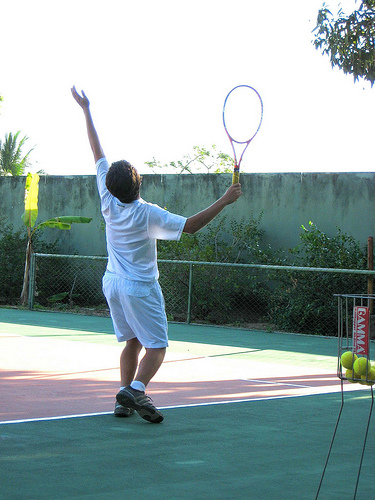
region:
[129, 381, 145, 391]
a short white sock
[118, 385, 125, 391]
a short white sock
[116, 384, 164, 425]
a brown and black tennis shoe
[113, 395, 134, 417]
a brown and black tennis shoe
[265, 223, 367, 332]
a large green bush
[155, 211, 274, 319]
a large green bush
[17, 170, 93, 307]
a large leafed plant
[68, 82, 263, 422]
a tennis player serving ball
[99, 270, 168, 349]
a pair of men's white shorts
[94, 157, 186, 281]
a man's short sleeve white t-shirt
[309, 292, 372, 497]
a metal basket with tennis balls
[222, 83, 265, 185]
a red black and yellow tennis racket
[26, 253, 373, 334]
a short chain link fence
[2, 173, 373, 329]
a tall concrete wall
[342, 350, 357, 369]
a bright yellow tennis ball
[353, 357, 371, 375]
a bright yellow tennis ball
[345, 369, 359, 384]
a bright yellow tennis ball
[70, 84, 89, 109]
A man's left hand.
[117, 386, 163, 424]
A man's right sneaker that is brown and black.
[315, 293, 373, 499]
A metal container that is holding tennis balls.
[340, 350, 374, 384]
Four tennis balls in a metal basket.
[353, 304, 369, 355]
A red sign with white letters that say GAMMA.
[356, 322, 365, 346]
Double white M's in GAMMA.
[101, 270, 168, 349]
White shorts on a man serving.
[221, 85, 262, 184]
A blue and red tennis racket.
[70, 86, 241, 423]
A man in all white serving a tennis ball.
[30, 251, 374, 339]
A long chain link fence.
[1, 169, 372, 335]
a white wall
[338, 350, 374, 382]
the green tennis balls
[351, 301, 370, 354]
a red and white sign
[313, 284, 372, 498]
the wire stand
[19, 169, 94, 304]
the palm tree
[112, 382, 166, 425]
the sneakers on the feet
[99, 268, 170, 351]
the pair of shorts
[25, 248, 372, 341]
a chain link fence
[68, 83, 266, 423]
a man on the court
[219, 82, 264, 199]
a tennis racket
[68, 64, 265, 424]
a man holding a tennis racket in the air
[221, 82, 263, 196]
a lightweight tennis racket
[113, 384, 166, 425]
a man's tennis shoes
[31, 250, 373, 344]
a small metal fence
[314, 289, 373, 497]
a bin holding tennis balls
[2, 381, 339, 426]
an out of bounds line on a tennis court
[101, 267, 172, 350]
a man's white shorts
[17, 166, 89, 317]
a small tree with large leaves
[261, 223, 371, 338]
a large shrub behind a fence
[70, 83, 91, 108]
a man's left hand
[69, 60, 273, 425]
man wearing a white shirt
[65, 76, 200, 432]
man wearing white shorts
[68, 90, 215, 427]
man wearing white socks